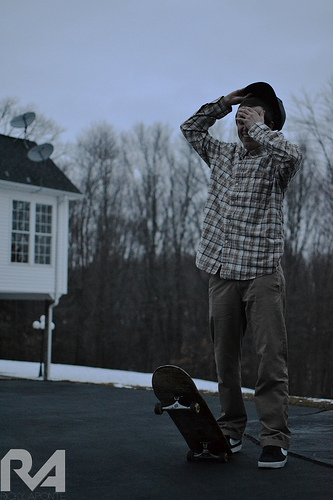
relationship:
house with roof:
[1, 133, 82, 334] [1, 129, 86, 199]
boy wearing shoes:
[199, 75, 304, 332] [207, 414, 299, 478]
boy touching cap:
[179, 81, 303, 469] [244, 80, 284, 126]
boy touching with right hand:
[179, 81, 303, 469] [235, 103, 262, 130]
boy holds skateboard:
[179, 81, 303, 469] [151, 364, 231, 466]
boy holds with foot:
[179, 81, 303, 469] [220, 426, 245, 452]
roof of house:
[2, 133, 85, 205] [2, 135, 95, 382]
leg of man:
[207, 272, 246, 453] [179, 82, 302, 468]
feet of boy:
[209, 419, 300, 472] [179, 81, 303, 469]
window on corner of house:
[11, 198, 54, 266] [0, 133, 86, 381]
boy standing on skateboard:
[179, 81, 303, 469] [151, 364, 231, 466]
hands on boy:
[206, 76, 272, 125] [180, 86, 325, 281]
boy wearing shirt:
[179, 81, 303, 469] [179, 97, 302, 278]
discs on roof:
[24, 142, 53, 161] [0, 135, 75, 191]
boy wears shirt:
[179, 81, 303, 469] [175, 92, 306, 283]